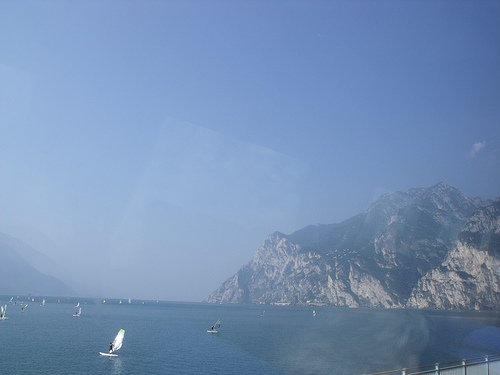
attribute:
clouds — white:
[468, 138, 486, 156]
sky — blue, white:
[2, 3, 498, 301]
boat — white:
[99, 327, 125, 357]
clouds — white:
[461, 134, 485, 164]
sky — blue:
[391, 105, 450, 157]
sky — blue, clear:
[244, 96, 374, 138]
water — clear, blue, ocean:
[268, 331, 416, 363]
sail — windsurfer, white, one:
[108, 325, 126, 361]